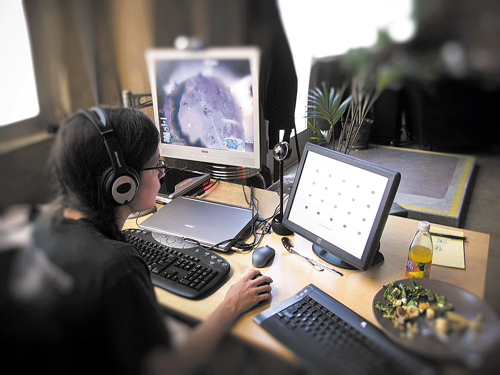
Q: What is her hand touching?
A: Mouse.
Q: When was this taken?
A: During the day.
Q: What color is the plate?
A: Grey.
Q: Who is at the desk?
A: A girl.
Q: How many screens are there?
A: Two.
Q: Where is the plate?
A: On the edge of the desk.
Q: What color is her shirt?
A: Black.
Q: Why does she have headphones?
A: To listen to the computer.